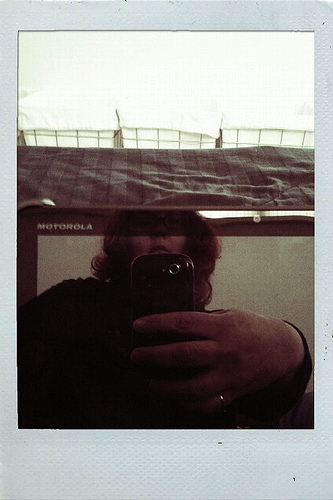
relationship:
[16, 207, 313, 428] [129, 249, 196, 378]
woman holds cellphone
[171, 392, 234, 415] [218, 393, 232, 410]
finger has ring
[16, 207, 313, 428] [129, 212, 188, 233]
woman wears glasses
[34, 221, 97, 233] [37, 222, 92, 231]
label says label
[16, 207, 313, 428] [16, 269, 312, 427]
woman wears shirt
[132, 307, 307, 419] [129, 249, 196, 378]
hand holds cellphone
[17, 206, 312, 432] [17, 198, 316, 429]
reflection on cellphone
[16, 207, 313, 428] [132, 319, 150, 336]
woman has finger nail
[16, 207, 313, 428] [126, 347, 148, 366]
woman has finger nail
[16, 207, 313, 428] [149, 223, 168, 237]
woman has nose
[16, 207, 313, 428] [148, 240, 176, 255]
woman has mouth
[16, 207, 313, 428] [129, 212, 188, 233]
woman has glasses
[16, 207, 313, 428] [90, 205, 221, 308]
woman has head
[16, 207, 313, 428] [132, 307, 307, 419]
woman has hand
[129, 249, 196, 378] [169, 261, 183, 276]
cellphone has camera lens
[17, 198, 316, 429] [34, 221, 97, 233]
cellphone has label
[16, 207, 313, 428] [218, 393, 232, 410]
woman has ring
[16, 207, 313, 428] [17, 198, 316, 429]
woman holds cellphone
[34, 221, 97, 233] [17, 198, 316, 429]
label on cellphone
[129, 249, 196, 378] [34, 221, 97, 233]
cellphone has label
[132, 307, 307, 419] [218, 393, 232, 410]
hand wears ring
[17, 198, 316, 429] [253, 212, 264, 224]
cellphone has camera spot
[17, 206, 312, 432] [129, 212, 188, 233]
reflection has glasses